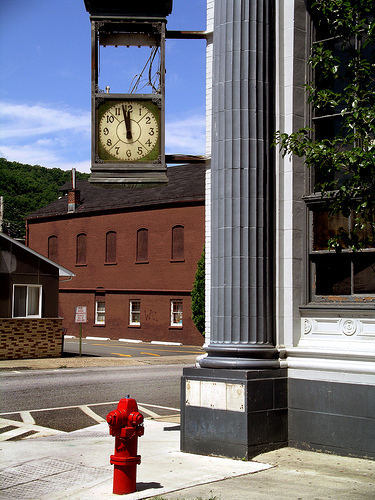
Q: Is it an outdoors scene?
A: Yes, it is outdoors.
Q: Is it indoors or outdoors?
A: It is outdoors.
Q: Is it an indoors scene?
A: No, it is outdoors.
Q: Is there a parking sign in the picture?
A: Yes, there is a parking sign.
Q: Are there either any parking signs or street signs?
A: Yes, there is a parking sign.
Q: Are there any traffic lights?
A: No, there are no traffic lights.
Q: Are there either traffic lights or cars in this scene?
A: No, there are no traffic lights or cars.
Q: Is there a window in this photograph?
A: Yes, there is a window.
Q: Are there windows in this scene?
A: Yes, there is a window.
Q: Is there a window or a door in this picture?
A: Yes, there is a window.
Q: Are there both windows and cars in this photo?
A: No, there is a window but no cars.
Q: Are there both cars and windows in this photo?
A: No, there is a window but no cars.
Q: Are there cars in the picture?
A: No, there are no cars.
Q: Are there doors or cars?
A: No, there are no cars or doors.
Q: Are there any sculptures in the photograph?
A: No, there are no sculptures.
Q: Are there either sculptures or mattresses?
A: No, there are no sculptures or mattresses.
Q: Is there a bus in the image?
A: No, there are no buses.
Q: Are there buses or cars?
A: No, there are no buses or cars.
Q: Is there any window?
A: Yes, there is a window.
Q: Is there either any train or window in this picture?
A: Yes, there is a window.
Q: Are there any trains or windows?
A: Yes, there is a window.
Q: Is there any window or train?
A: Yes, there is a window.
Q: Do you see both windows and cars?
A: No, there is a window but no cars.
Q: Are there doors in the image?
A: No, there are no doors.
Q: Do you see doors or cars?
A: No, there are no doors or cars.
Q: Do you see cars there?
A: No, there are no cars.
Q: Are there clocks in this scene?
A: Yes, there is a clock.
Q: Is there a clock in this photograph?
A: Yes, there is a clock.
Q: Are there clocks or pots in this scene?
A: Yes, there is a clock.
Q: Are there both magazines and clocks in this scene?
A: No, there is a clock but no magazines.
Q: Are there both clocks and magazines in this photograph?
A: No, there is a clock but no magazines.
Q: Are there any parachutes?
A: No, there are no parachutes.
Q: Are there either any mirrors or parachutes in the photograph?
A: No, there are no parachutes or mirrors.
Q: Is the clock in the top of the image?
A: Yes, the clock is in the top of the image.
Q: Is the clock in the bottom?
A: No, the clock is in the top of the image.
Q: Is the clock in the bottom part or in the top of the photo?
A: The clock is in the top of the image.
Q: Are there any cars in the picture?
A: No, there are no cars.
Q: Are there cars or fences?
A: No, there are no cars or fences.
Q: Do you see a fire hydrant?
A: Yes, there is a fire hydrant.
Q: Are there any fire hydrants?
A: Yes, there is a fire hydrant.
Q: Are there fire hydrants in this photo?
A: Yes, there is a fire hydrant.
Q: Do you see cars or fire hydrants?
A: Yes, there is a fire hydrant.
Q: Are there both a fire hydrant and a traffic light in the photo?
A: No, there is a fire hydrant but no traffic lights.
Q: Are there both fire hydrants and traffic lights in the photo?
A: No, there is a fire hydrant but no traffic lights.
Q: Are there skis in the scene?
A: No, there are no skis.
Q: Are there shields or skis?
A: No, there are no skis or shields.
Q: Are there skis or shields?
A: No, there are no skis or shields.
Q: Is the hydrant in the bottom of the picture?
A: Yes, the hydrant is in the bottom of the image.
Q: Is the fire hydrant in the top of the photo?
A: No, the fire hydrant is in the bottom of the image.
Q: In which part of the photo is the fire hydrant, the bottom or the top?
A: The fire hydrant is in the bottom of the image.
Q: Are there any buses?
A: No, there are no buses.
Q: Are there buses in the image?
A: No, there are no buses.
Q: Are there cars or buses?
A: No, there are no buses or cars.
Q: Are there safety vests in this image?
A: No, there are no safety vests.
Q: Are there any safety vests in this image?
A: No, there are no safety vests.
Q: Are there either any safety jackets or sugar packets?
A: No, there are no safety jackets or sugar packets.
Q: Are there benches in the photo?
A: No, there are no benches.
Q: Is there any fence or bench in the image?
A: No, there are no benches or fences.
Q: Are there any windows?
A: Yes, there are windows.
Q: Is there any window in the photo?
A: Yes, there are windows.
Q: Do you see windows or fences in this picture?
A: Yes, there are windows.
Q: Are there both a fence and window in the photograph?
A: No, there are windows but no fences.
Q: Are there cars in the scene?
A: No, there are no cars.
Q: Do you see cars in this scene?
A: No, there are no cars.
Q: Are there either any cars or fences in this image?
A: No, there are no cars or fences.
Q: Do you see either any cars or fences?
A: No, there are no cars or fences.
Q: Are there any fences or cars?
A: No, there are no cars or fences.